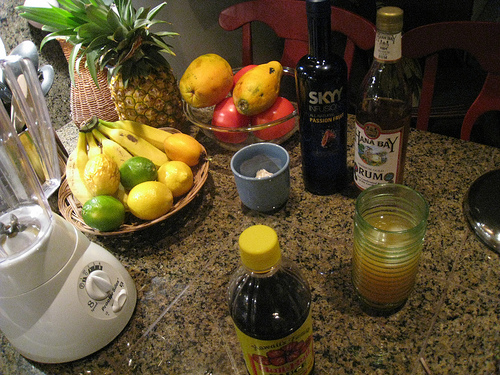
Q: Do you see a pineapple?
A: Yes, there is a pineapple.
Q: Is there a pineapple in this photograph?
A: Yes, there is a pineapple.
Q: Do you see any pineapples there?
A: Yes, there is a pineapple.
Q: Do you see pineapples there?
A: Yes, there is a pineapple.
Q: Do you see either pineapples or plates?
A: Yes, there is a pineapple.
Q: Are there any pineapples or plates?
A: Yes, there is a pineapple.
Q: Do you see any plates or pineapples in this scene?
A: Yes, there is a pineapple.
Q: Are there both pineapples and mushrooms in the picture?
A: No, there is a pineapple but no mushrooms.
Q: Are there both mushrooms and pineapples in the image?
A: No, there is a pineapple but no mushrooms.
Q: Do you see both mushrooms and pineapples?
A: No, there is a pineapple but no mushrooms.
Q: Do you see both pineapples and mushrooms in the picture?
A: No, there is a pineapple but no mushrooms.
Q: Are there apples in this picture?
A: No, there are no apples.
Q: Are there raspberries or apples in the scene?
A: No, there are no apples or raspberries.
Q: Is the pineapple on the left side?
A: Yes, the pineapple is on the left of the image.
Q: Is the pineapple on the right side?
A: No, the pineapple is on the left of the image.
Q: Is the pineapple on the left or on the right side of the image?
A: The pineapple is on the left of the image.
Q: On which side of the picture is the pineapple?
A: The pineapple is on the left of the image.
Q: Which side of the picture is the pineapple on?
A: The pineapple is on the left of the image.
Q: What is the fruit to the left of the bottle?
A: The fruit is a pineapple.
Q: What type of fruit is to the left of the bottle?
A: The fruit is a pineapple.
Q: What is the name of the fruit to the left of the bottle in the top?
A: The fruit is a pineapple.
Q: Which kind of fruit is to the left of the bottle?
A: The fruit is a pineapple.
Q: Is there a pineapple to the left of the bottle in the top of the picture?
A: Yes, there is a pineapple to the left of the bottle.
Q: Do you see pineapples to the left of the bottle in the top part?
A: Yes, there is a pineapple to the left of the bottle.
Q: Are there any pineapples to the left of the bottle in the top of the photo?
A: Yes, there is a pineapple to the left of the bottle.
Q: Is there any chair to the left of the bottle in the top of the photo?
A: No, there is a pineapple to the left of the bottle.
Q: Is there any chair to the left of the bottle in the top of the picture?
A: No, there is a pineapple to the left of the bottle.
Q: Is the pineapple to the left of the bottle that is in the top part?
A: Yes, the pineapple is to the left of the bottle.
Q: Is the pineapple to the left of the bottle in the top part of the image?
A: Yes, the pineapple is to the left of the bottle.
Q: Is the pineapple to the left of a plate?
A: No, the pineapple is to the left of the bottle.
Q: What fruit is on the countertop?
A: The fruit is a pineapple.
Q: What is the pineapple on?
A: The pineapple is on the countertop.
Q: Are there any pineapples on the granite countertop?
A: Yes, there is a pineapple on the countertop.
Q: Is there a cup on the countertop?
A: No, there is a pineapple on the countertop.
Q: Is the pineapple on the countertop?
A: Yes, the pineapple is on the countertop.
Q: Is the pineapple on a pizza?
A: No, the pineapple is on the countertop.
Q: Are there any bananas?
A: Yes, there are bananas.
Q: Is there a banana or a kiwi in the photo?
A: Yes, there are bananas.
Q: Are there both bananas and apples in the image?
A: No, there are bananas but no apples.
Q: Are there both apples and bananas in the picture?
A: No, there are bananas but no apples.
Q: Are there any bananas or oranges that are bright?
A: Yes, the bananas are bright.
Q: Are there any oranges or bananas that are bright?
A: Yes, the bananas are bright.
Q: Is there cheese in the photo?
A: No, there is no cheese.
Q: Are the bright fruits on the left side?
A: Yes, the bananas are on the left of the image.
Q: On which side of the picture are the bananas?
A: The bananas are on the left of the image.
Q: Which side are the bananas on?
A: The bananas are on the left of the image.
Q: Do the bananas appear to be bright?
A: Yes, the bananas are bright.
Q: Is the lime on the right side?
A: No, the lime is on the left of the image.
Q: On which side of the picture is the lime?
A: The lime is on the left of the image.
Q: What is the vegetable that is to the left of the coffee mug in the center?
A: The vegetable is a lime.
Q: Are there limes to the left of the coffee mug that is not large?
A: Yes, there is a lime to the left of the coffee mug.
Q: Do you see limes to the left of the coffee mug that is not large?
A: Yes, there is a lime to the left of the coffee mug.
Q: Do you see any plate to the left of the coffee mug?
A: No, there is a lime to the left of the coffee mug.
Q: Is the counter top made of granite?
A: Yes, the counter top is made of granite.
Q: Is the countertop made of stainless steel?
A: No, the countertop is made of granite.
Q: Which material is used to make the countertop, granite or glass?
A: The countertop is made of granite.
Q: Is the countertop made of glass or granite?
A: The countertop is made of granite.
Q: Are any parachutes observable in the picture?
A: No, there are no parachutes.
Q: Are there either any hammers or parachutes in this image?
A: No, there are no parachutes or hammers.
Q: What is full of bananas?
A: The basket is full of bananas.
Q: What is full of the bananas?
A: The basket is full of bananas.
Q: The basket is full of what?
A: The basket is full of bananas.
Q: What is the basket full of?
A: The basket is full of bananas.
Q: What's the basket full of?
A: The basket is full of bananas.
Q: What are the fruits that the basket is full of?
A: The fruits are bananas.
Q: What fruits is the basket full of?
A: The basket is full of bananas.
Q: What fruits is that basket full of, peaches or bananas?
A: The basket is full of bananas.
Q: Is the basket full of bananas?
A: Yes, the basket is full of bananas.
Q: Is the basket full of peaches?
A: No, the basket is full of bananas.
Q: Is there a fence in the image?
A: No, there are no fences.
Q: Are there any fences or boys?
A: No, there are no fences or boys.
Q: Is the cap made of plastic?
A: Yes, the cap is made of plastic.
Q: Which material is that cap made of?
A: The cap is made of plastic.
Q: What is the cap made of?
A: The cap is made of plastic.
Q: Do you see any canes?
A: No, there are no canes.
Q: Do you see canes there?
A: No, there are no canes.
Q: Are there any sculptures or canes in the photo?
A: No, there are no canes or sculptures.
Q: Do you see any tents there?
A: No, there are no tents.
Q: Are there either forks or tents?
A: No, there are no tents or forks.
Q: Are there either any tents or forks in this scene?
A: No, there are no tents or forks.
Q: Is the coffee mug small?
A: Yes, the coffee mug is small.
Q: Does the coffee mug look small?
A: Yes, the coffee mug is small.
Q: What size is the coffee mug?
A: The coffee mug is small.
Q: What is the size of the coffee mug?
A: The coffee mug is small.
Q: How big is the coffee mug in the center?
A: The coffee mug is small.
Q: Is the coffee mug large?
A: No, the coffee mug is small.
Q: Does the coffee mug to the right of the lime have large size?
A: No, the coffee mug is small.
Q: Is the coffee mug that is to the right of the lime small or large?
A: The coffee mug is small.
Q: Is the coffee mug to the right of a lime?
A: Yes, the coffee mug is to the right of a lime.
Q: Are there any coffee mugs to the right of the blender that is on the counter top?
A: Yes, there is a coffee mug to the right of the blender.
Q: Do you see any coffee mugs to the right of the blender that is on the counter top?
A: Yes, there is a coffee mug to the right of the blender.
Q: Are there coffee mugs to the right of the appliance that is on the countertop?
A: Yes, there is a coffee mug to the right of the blender.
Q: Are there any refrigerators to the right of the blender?
A: No, there is a coffee mug to the right of the blender.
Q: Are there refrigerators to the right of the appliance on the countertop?
A: No, there is a coffee mug to the right of the blender.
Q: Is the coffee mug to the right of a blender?
A: Yes, the coffee mug is to the right of a blender.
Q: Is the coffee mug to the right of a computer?
A: No, the coffee mug is to the right of a blender.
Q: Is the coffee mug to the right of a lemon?
A: Yes, the coffee mug is to the right of a lemon.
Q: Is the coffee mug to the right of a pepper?
A: No, the coffee mug is to the right of a lemon.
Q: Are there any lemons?
A: Yes, there is a lemon.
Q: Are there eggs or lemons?
A: Yes, there is a lemon.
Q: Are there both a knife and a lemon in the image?
A: No, there is a lemon but no knives.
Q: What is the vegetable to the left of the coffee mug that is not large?
A: The vegetable is a lemon.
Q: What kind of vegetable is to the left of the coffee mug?
A: The vegetable is a lemon.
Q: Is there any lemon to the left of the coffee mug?
A: Yes, there is a lemon to the left of the coffee mug.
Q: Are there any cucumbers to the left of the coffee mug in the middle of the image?
A: No, there is a lemon to the left of the coffee mug.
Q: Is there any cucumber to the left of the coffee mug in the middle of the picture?
A: No, there is a lemon to the left of the coffee mug.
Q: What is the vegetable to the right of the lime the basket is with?
A: The vegetable is a lemon.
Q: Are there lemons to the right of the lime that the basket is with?
A: Yes, there is a lemon to the right of the lime.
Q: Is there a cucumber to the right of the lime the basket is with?
A: No, there is a lemon to the right of the lime.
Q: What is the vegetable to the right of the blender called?
A: The vegetable is a lemon.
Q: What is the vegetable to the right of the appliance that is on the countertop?
A: The vegetable is a lemon.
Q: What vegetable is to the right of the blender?
A: The vegetable is a lemon.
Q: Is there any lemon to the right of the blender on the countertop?
A: Yes, there is a lemon to the right of the blender.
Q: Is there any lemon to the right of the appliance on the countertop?
A: Yes, there is a lemon to the right of the blender.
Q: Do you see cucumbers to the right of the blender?
A: No, there is a lemon to the right of the blender.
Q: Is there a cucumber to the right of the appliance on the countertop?
A: No, there is a lemon to the right of the blender.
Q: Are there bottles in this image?
A: Yes, there is a bottle.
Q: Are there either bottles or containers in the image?
A: Yes, there is a bottle.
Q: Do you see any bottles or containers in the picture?
A: Yes, there is a bottle.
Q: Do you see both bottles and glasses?
A: Yes, there are both a bottle and glasses.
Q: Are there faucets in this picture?
A: No, there are no faucets.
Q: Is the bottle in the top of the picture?
A: Yes, the bottle is in the top of the image.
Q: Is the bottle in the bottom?
A: No, the bottle is in the top of the image.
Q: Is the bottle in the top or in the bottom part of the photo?
A: The bottle is in the top of the image.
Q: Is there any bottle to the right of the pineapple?
A: Yes, there is a bottle to the right of the pineapple.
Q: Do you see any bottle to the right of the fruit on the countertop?
A: Yes, there is a bottle to the right of the pineapple.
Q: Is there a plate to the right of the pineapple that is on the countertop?
A: No, there is a bottle to the right of the pineapple.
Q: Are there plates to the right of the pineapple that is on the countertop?
A: No, there is a bottle to the right of the pineapple.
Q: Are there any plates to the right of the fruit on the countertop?
A: No, there is a bottle to the right of the pineapple.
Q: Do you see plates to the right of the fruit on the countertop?
A: No, there is a bottle to the right of the pineapple.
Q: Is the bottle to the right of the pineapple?
A: Yes, the bottle is to the right of the pineapple.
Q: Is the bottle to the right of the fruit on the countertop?
A: Yes, the bottle is to the right of the pineapple.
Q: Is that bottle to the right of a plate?
A: No, the bottle is to the right of the pineapple.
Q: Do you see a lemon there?
A: Yes, there is a lemon.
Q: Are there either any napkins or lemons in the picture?
A: Yes, there is a lemon.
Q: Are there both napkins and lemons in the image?
A: No, there is a lemon but no napkins.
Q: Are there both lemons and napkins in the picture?
A: No, there is a lemon but no napkins.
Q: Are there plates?
A: No, there are no plates.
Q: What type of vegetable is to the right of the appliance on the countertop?
A: The vegetable is a lemon.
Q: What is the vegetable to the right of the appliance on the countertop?
A: The vegetable is a lemon.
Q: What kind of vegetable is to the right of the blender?
A: The vegetable is a lemon.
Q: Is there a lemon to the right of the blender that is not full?
A: Yes, there is a lemon to the right of the blender.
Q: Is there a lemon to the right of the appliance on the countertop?
A: Yes, there is a lemon to the right of the blender.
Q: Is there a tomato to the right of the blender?
A: No, there is a lemon to the right of the blender.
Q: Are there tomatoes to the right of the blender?
A: No, there is a lemon to the right of the blender.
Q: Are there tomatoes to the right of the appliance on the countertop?
A: No, there is a lemon to the right of the blender.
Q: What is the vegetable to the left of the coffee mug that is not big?
A: The vegetable is a lemon.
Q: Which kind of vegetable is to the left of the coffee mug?
A: The vegetable is a lemon.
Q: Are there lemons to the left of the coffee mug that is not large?
A: Yes, there is a lemon to the left of the coffee mug.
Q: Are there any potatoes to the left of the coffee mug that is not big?
A: No, there is a lemon to the left of the coffee mug.